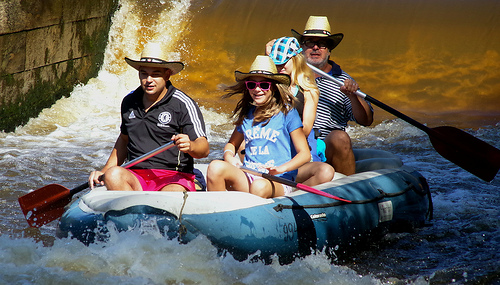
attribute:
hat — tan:
[120, 40, 185, 81]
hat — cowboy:
[117, 35, 192, 82]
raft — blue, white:
[76, 169, 434, 244]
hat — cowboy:
[283, 8, 343, 52]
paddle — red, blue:
[15, 127, 197, 235]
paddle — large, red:
[19, 135, 176, 232]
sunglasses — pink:
[243, 79, 271, 91]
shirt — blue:
[226, 102, 322, 182]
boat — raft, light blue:
[133, 156, 401, 241]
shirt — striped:
[310, 60, 354, 140]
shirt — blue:
[233, 99, 303, 186]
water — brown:
[352, 47, 474, 84]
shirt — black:
[112, 84, 208, 169]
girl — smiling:
[200, 50, 310, 198]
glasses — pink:
[240, 76, 272, 91]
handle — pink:
[61, 136, 182, 195]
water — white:
[1, 211, 361, 280]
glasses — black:
[294, 38, 330, 51]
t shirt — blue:
[239, 104, 299, 176]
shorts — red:
[122, 168, 200, 208]